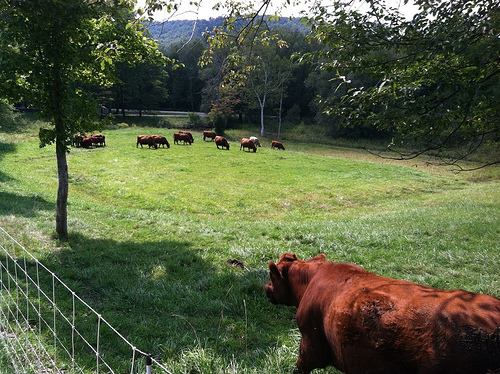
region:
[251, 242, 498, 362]
a brown cow walking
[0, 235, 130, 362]
a thin metal fence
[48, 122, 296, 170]
a herd of cattle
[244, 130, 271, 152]
a pale colored cow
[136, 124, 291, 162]
a few cows grazing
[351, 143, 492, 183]
a few bare tree branches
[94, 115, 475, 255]
a green meadow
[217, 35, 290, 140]
a tree with a white trunk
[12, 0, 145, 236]
a tree with thick foliage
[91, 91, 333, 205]
a road near a field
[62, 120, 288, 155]
THE COWS ARE GRAZING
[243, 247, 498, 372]
THE COW IS REDDISH BROWN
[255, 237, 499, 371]
THE COW IS ALONE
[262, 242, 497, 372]
THE COW IS DIRTY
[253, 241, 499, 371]
THIS IS A COW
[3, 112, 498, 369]
THE GREEN GRASS IS LUSH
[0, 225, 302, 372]
THE SHADOW IS ON THE GROUND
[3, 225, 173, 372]
THE FENCE IS MADE OF WIRE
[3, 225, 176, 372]
THE FENCE IS NEXT TO THE COW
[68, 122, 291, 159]
THE COWS ARE STANDING IN A GROUP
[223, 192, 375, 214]
The grass is green.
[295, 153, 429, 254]
The grass is lush.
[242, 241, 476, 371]
The cow is brown.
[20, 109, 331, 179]
The cows are grazing.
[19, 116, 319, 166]
The cows are standing.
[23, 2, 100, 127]
The tree is tall.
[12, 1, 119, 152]
The tree is leafy.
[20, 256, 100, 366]
the fence is white.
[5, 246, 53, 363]
The fence is short.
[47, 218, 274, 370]
The tree is casting a shadow.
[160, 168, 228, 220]
grass next to animals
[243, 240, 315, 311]
head of the animal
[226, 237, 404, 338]
brown fur on cow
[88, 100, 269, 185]
group of cows together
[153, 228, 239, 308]
shadow on the ground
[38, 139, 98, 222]
branch of the tree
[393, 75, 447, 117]
leaves on the tree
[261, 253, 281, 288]
ear of the cow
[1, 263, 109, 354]
fence next to cow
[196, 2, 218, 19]
sky above the ground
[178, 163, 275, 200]
this is the grass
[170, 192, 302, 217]
the grass is green in color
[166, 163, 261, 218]
the grass is short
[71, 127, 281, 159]
these are some cows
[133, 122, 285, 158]
the cows are grazing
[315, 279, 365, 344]
the fur is brown in color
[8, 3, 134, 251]
this is a tree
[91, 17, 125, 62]
the leaves are green in color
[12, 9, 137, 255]
the tree is short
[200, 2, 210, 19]
this is the sky